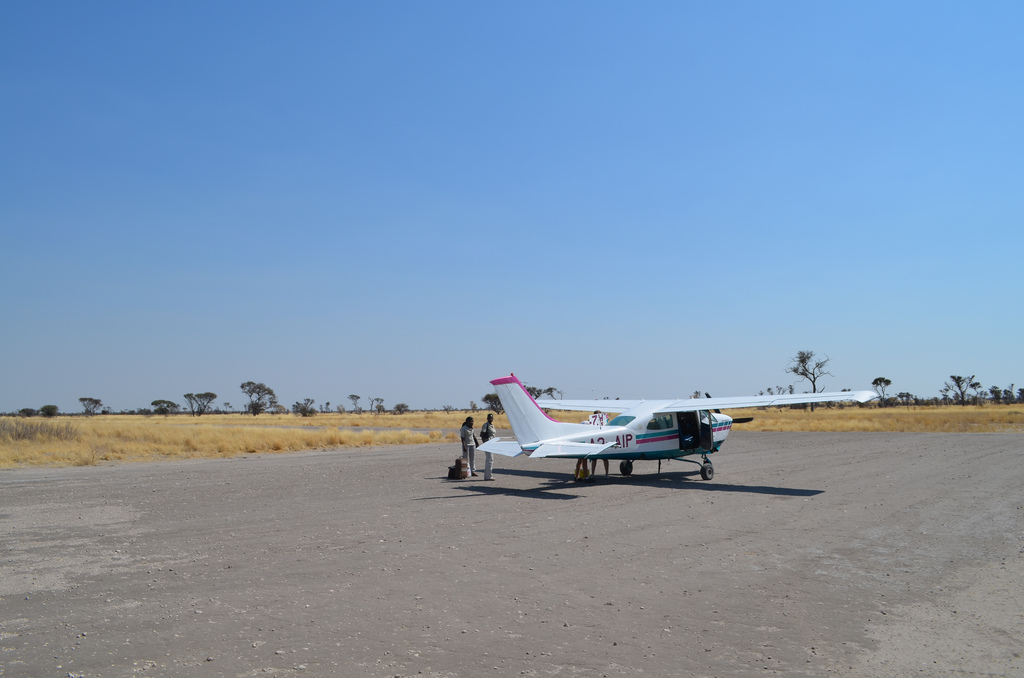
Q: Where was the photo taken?
A: On a runway.